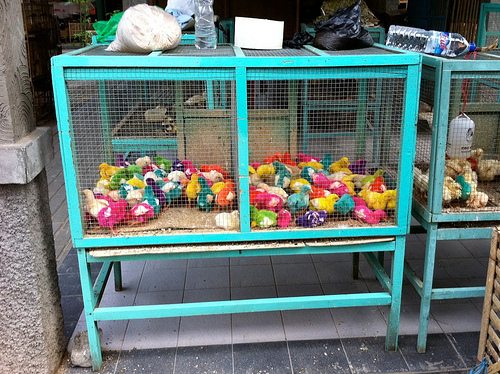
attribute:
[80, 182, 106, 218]
bird — small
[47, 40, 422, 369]
cage — small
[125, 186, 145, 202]
bird — small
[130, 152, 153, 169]
bird — small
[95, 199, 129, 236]
bird — small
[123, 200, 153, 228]
bird — small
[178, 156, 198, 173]
bird — small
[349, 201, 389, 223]
bird — small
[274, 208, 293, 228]
bird — small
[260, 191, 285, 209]
bird — small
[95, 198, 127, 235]
bird — pink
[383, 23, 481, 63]
bottle — clear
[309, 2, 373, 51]
bag — black